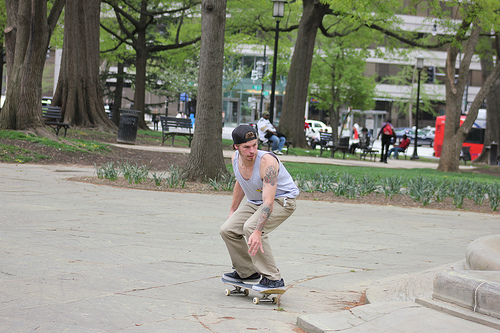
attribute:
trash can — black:
[113, 105, 145, 149]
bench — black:
[38, 93, 71, 130]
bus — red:
[420, 109, 492, 166]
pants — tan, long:
[218, 193, 298, 283]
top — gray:
[229, 149, 299, 201]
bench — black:
[158, 112, 194, 147]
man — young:
[219, 120, 299, 306]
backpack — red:
[378, 124, 398, 141]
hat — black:
[228, 125, 261, 144]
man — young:
[208, 115, 328, 284]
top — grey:
[228, 152, 308, 207]